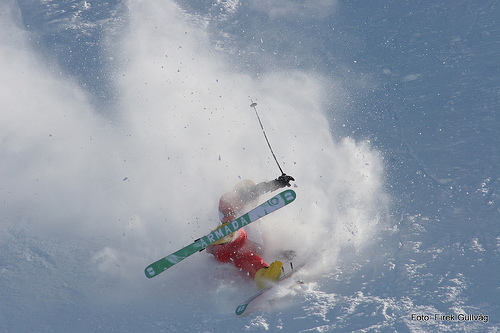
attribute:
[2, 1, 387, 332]
snow splash — white, large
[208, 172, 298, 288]
man — skier, skiing, skiing outside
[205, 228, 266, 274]
pants — red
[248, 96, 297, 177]
pole — metal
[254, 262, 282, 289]
shoe — yellow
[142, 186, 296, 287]
ski — green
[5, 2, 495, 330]
field — covered in snow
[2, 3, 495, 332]
snow — white